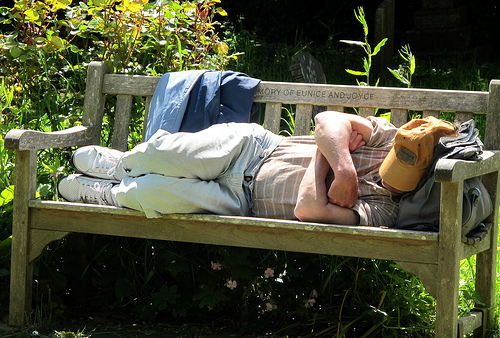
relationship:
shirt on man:
[248, 117, 404, 228] [53, 104, 473, 232]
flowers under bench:
[153, 242, 343, 323] [1, 59, 499, 336]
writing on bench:
[256, 82, 385, 104] [1, 59, 499, 336]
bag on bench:
[401, 117, 490, 240] [1, 59, 499, 336]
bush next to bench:
[1, 2, 247, 221] [1, 59, 499, 336]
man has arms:
[53, 104, 473, 232] [290, 99, 386, 231]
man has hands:
[53, 104, 473, 232] [331, 129, 370, 208]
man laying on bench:
[53, 104, 473, 232] [1, 59, 499, 336]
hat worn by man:
[378, 115, 456, 196] [53, 104, 473, 232]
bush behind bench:
[1, 2, 247, 221] [1, 59, 499, 336]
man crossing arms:
[53, 104, 473, 232] [290, 99, 386, 231]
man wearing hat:
[53, 104, 473, 232] [378, 115, 456, 196]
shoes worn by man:
[49, 138, 128, 212] [53, 104, 473, 232]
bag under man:
[401, 117, 490, 240] [53, 104, 473, 232]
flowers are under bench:
[153, 242, 343, 323] [1, 59, 499, 336]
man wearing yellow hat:
[53, 104, 473, 232] [378, 115, 456, 196]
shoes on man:
[49, 138, 128, 212] [53, 104, 473, 232]